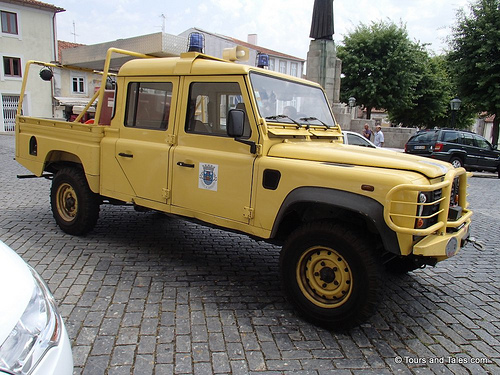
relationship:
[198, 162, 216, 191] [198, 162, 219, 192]
decal has decal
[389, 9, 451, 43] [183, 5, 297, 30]
clouds in sky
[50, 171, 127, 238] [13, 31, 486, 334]
rear wheel in car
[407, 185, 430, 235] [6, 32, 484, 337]
headlight in car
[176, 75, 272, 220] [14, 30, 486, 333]
door on truck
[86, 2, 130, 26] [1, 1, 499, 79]
clouds in blue sky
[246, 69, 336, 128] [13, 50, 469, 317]
windshield on vehicle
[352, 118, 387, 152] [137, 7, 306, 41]
people in background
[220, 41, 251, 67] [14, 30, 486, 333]
speaker system mounted on truck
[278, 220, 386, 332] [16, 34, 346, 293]
sheel on truck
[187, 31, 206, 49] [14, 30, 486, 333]
blue light on truck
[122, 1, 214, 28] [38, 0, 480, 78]
clouds in sky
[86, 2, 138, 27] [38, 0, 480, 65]
clouds in sky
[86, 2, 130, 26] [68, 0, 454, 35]
clouds in blue sky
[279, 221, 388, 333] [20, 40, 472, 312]
tire on truck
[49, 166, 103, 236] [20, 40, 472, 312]
rear wheel on truck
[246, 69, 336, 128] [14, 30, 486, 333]
windshield on truck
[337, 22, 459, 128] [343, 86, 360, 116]
trees behind lights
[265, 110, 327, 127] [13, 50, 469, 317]
wipers of vehicle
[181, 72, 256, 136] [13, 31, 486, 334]
window of car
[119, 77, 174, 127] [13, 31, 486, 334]
window of car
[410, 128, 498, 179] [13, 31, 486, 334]
black suv parked behind car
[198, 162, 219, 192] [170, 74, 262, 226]
decal on door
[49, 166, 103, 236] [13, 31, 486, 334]
rear wheel on car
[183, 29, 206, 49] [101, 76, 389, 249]
blue light on truck